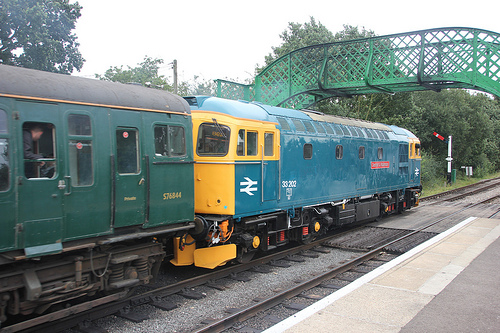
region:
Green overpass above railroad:
[212, 25, 497, 96]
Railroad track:
[0, 176, 496, 327]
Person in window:
[20, 120, 53, 180]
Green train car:
[0, 62, 191, 315]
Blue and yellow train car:
[186, 95, 416, 270]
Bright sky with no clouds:
[0, 0, 497, 93]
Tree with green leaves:
[0, 0, 85, 76]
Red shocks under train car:
[265, 227, 318, 250]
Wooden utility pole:
[156, 52, 186, 92]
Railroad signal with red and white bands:
[431, 128, 460, 185]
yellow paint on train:
[204, 179, 214, 196]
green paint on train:
[303, 173, 331, 189]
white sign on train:
[236, 175, 260, 201]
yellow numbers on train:
[155, 192, 187, 200]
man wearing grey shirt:
[28, 136, 33, 147]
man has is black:
[32, 125, 39, 132]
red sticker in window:
[122, 126, 131, 139]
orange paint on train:
[219, 222, 230, 234]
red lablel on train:
[371, 159, 376, 168]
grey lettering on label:
[372, 162, 390, 167]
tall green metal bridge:
[212, 24, 499, 103]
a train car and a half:
[0, 67, 426, 320]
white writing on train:
[237, 172, 259, 198]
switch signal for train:
[430, 126, 457, 184]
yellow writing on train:
[161, 190, 182, 200]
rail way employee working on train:
[22, 120, 54, 175]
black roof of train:
[2, 61, 192, 117]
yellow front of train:
[194, 110, 276, 217]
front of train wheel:
[234, 239, 256, 266]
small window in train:
[303, 142, 313, 159]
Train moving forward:
[0, 66, 427, 328]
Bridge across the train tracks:
[211, 28, 498, 102]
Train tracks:
[7, 178, 498, 332]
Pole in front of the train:
[445, 128, 456, 186]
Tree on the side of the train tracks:
[0, 1, 87, 82]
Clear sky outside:
[1, 3, 498, 105]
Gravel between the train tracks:
[25, 245, 366, 332]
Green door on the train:
[110, 116, 148, 231]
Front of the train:
[171, 95, 426, 272]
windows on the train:
[234, 127, 265, 157]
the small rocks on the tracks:
[200, 300, 235, 308]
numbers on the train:
[281, 178, 304, 187]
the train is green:
[10, 102, 195, 232]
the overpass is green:
[335, 56, 420, 78]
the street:
[410, 266, 480, 312]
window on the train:
[295, 141, 316, 157]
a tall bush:
[295, 18, 325, 43]